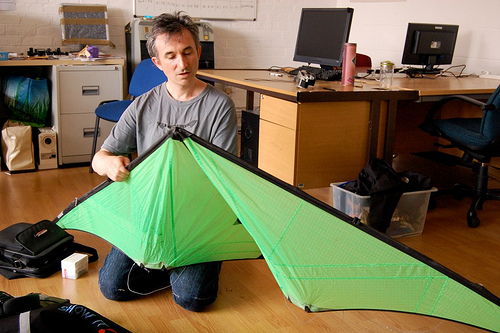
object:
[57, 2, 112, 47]
computer screen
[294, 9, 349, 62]
monitor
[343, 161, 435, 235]
jacket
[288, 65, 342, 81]
keyboard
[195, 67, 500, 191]
desk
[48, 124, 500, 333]
kite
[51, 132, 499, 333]
black edge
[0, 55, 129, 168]
desk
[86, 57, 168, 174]
chair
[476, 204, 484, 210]
wheels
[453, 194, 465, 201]
wheels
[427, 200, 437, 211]
wheels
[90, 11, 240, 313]
man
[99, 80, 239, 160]
shirt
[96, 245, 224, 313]
jeans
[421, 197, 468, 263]
ground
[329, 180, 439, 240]
bin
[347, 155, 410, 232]
item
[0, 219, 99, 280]
bag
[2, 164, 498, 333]
floor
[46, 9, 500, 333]
man kite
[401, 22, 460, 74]
computer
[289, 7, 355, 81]
computer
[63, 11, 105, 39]
monitor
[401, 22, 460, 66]
monitor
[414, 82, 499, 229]
chair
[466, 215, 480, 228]
wheel